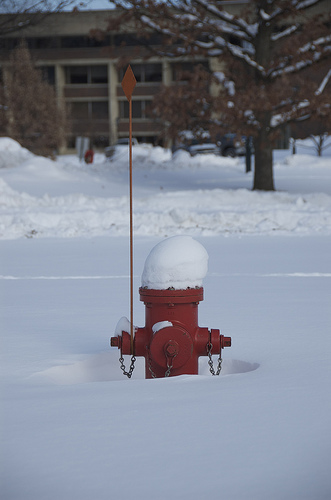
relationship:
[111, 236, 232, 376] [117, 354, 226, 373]
fire hydrant has chain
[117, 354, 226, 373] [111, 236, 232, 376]
chain in fire hydrant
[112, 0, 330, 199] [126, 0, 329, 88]
tree has branches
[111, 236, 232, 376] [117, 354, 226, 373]
hydrant has chain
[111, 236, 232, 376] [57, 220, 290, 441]
fire hydrant on snow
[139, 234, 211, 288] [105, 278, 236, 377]
snow on fire hydrant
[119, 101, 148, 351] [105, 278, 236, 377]
pole side fire hydrant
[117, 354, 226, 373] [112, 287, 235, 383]
chain on fire hydrant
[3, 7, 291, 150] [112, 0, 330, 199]
building back tree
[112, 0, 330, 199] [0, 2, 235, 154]
tree front building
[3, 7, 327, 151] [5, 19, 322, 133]
building on background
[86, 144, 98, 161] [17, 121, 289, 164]
person on background